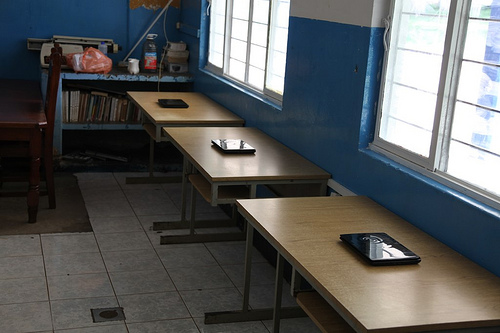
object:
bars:
[361, 0, 500, 206]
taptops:
[165, 122, 329, 183]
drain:
[90, 310, 121, 321]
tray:
[151, 148, 235, 231]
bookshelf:
[42, 70, 192, 171]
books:
[61, 90, 142, 122]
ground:
[413, 176, 448, 214]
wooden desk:
[203, 192, 498, 332]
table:
[0, 75, 46, 227]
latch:
[380, 13, 391, 52]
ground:
[331, 135, 375, 193]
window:
[367, 0, 499, 210]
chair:
[0, 39, 63, 222]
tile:
[0, 172, 301, 333]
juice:
[144, 33, 159, 73]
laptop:
[339, 232, 421, 265]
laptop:
[211, 138, 256, 154]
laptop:
[157, 98, 189, 108]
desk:
[232, 197, 500, 333]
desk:
[161, 125, 330, 181]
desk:
[125, 91, 246, 124]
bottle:
[141, 34, 156, 73]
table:
[228, 196, 498, 332]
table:
[162, 126, 333, 180]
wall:
[1, 0, 181, 160]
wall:
[172, 0, 499, 270]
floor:
[1, 149, 318, 331]